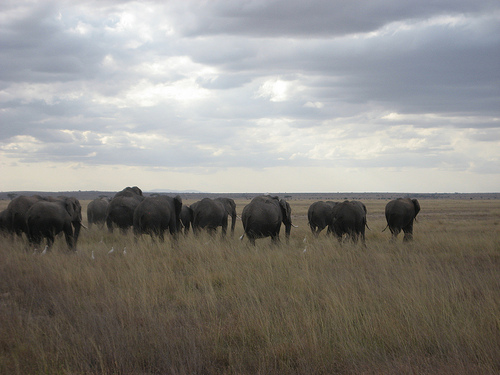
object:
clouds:
[83, 47, 201, 103]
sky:
[179, 45, 296, 80]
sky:
[175, 132, 269, 173]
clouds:
[304, 139, 383, 175]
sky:
[385, 147, 482, 176]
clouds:
[421, 130, 495, 174]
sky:
[299, 147, 401, 171]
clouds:
[96, 111, 146, 150]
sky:
[397, 161, 476, 187]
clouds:
[139, 49, 197, 82]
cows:
[381, 197, 421, 243]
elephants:
[189, 197, 237, 238]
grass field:
[113, 244, 480, 358]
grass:
[193, 296, 493, 362]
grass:
[28, 253, 323, 335]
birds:
[107, 247, 114, 255]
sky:
[11, 32, 78, 69]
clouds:
[14, 28, 89, 68]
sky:
[38, 139, 155, 178]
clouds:
[417, 108, 496, 157]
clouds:
[386, 13, 456, 62]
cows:
[332, 200, 367, 248]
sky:
[27, 161, 92, 184]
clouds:
[292, 0, 405, 40]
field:
[0, 243, 500, 375]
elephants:
[240, 195, 298, 248]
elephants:
[86, 194, 111, 229]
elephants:
[0, 194, 89, 252]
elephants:
[106, 186, 145, 235]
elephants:
[306, 200, 336, 237]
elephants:
[23, 200, 74, 252]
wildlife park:
[0, 183, 500, 375]